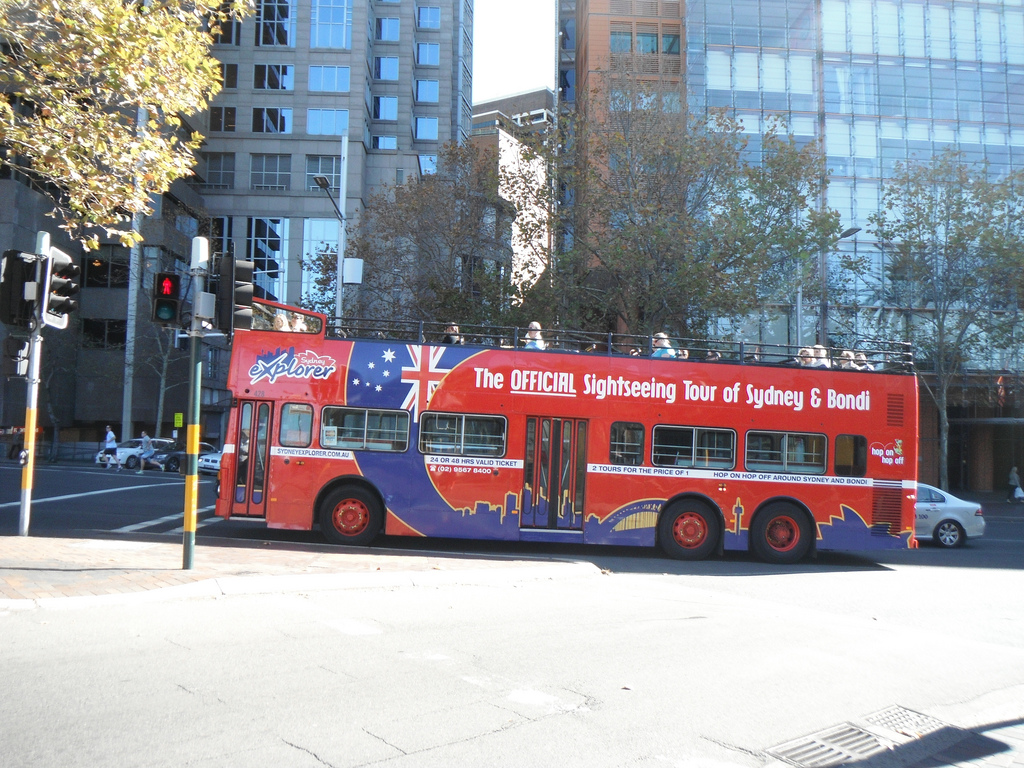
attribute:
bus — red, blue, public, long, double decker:
[220, 323, 918, 566]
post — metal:
[185, 351, 203, 580]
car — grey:
[916, 485, 975, 540]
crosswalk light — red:
[144, 271, 181, 328]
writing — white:
[464, 366, 879, 406]